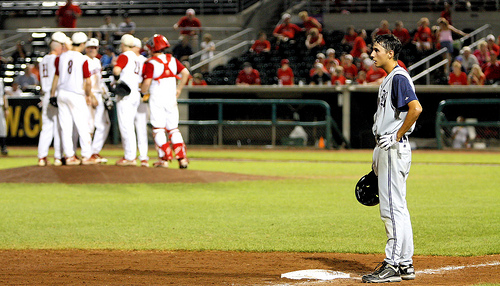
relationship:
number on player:
[63, 58, 75, 76] [135, 29, 196, 168]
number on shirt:
[63, 58, 75, 76] [370, 65, 417, 135]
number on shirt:
[63, 58, 75, 76] [53, 48, 90, 95]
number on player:
[63, 58, 75, 76] [360, 34, 417, 284]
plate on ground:
[280, 263, 357, 283] [1, 140, 498, 282]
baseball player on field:
[47, 28, 102, 168] [6, 148, 498, 284]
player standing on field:
[144, 39, 193, 167] [6, 148, 498, 284]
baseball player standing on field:
[113, 37, 153, 164] [6, 148, 498, 284]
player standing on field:
[344, 21, 459, 283] [6, 148, 498, 284]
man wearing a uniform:
[142, 30, 190, 169] [375, 64, 420, 280]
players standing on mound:
[30, 23, 210, 135] [0, 116, 232, 230]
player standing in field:
[368, 39, 420, 282] [24, 18, 499, 262]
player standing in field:
[57, 34, 94, 164] [6, 148, 498, 284]